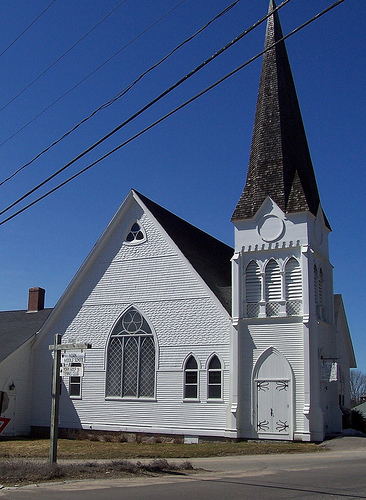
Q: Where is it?
A: This is at the church.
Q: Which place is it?
A: It is a church.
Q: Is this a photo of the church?
A: Yes, it is showing the church.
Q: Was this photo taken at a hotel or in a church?
A: It was taken at a church.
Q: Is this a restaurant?
A: No, it is a church.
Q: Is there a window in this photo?
A: Yes, there is a window.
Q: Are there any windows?
A: Yes, there is a window.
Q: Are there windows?
A: Yes, there is a window.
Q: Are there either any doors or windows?
A: Yes, there is a window.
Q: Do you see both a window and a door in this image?
A: Yes, there are both a window and a door.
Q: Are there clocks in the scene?
A: No, there are no clocks.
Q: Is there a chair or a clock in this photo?
A: No, there are no clocks or chairs.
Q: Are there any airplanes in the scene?
A: No, there are no airplanes.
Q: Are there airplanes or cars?
A: No, there are no airplanes or cars.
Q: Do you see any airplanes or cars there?
A: No, there are no airplanes or cars.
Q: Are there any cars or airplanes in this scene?
A: No, there are no airplanes or cars.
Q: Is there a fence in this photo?
A: No, there are no fences.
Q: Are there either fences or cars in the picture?
A: No, there are no fences or cars.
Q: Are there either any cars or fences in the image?
A: No, there are no fences or cars.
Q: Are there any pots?
A: No, there are no pots.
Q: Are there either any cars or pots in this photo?
A: No, there are no pots or cars.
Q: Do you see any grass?
A: Yes, there is grass.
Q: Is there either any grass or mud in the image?
A: Yes, there is grass.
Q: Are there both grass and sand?
A: No, there is grass but no sand.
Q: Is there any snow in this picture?
A: No, there is no snow.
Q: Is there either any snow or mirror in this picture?
A: No, there are no snow or mirrors.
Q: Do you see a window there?
A: Yes, there are windows.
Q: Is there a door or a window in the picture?
A: Yes, there are windows.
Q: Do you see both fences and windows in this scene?
A: No, there are windows but no fences.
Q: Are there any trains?
A: No, there are no trains.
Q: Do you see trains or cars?
A: No, there are no trains or cars.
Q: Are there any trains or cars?
A: No, there are no trains or cars.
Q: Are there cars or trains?
A: No, there are no trains or cars.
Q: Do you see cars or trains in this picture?
A: No, there are no trains or cars.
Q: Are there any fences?
A: No, there are no fences.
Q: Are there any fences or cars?
A: No, there are no fences or cars.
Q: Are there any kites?
A: No, there are no kites.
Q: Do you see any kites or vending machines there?
A: No, there are no kites or vending machines.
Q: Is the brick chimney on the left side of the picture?
A: Yes, the chimney is on the left of the image.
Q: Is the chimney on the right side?
A: No, the chimney is on the left of the image.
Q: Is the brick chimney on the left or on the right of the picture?
A: The chimney is on the left of the image.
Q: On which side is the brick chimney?
A: The chimney is on the left of the image.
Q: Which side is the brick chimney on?
A: The chimney is on the left of the image.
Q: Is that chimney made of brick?
A: Yes, the chimney is made of brick.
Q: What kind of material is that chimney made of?
A: The chimney is made of brick.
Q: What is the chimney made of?
A: The chimney is made of brick.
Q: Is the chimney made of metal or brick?
A: The chimney is made of brick.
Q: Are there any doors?
A: Yes, there is a door.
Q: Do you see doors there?
A: Yes, there is a door.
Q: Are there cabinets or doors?
A: Yes, there is a door.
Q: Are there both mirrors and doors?
A: No, there is a door but no mirrors.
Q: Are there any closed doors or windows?
A: Yes, there is a closed door.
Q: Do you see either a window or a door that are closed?
A: Yes, the door is closed.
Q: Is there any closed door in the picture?
A: Yes, there is a closed door.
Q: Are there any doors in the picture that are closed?
A: Yes, there is a door that is closed.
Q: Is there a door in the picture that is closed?
A: Yes, there is a door that is closed.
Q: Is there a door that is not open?
A: Yes, there is an closed door.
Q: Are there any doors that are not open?
A: Yes, there is an closed door.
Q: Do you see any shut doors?
A: Yes, there is a shut door.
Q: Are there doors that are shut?
A: Yes, there is a door that is shut.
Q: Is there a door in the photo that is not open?
A: Yes, there is an shut door.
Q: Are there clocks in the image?
A: No, there are no clocks.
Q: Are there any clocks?
A: No, there are no clocks.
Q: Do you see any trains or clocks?
A: No, there are no clocks or trains.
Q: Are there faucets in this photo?
A: No, there are no faucets.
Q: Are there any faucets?
A: No, there are no faucets.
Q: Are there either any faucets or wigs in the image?
A: No, there are no faucets or wigs.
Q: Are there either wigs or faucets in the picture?
A: No, there are no faucets or wigs.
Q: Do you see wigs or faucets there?
A: No, there are no faucets or wigs.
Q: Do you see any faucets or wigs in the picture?
A: No, there are no faucets or wigs.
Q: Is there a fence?
A: No, there are no fences.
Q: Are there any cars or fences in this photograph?
A: No, there are no fences or cars.